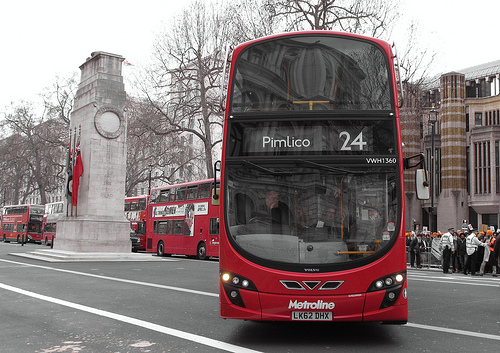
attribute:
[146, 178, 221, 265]
bus — red, double decker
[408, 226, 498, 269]
people — grouped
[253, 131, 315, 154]
letters — pimlico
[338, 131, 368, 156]
numbers — route number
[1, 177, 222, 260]
buses — lined up, outdoors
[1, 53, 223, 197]
buildings — in a row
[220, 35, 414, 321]
bus — red, turning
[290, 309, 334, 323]
license plate — white, black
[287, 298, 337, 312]
metroline — white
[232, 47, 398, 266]
windshield — reflective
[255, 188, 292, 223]
bus driver — man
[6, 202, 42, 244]
bus — red, distant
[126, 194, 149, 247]
bus — hidden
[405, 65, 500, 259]
building — brown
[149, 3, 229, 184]
tree — bare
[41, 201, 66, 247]
passenger bus — red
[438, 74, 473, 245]
pillar — brown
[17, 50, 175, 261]
monument — grey, stone